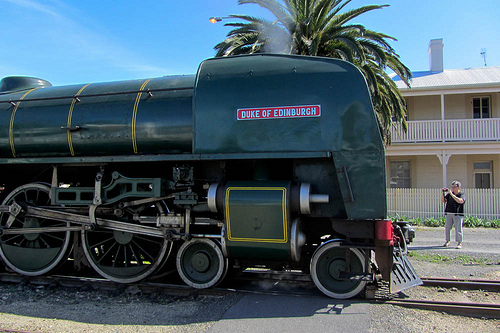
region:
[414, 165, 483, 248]
a man taking a picture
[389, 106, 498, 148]
the railings are white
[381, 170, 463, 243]
the railings are white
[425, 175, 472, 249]
Woman taking a picture.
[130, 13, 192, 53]
Bright blue sky above.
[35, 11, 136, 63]
Some light clouds in the sky.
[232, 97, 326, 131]
The name of the train.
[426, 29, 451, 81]
Chimney on the roof.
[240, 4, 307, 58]
Steam coming from the train.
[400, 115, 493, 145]
White balcony railing on the second floor.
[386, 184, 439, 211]
White fence in the yard.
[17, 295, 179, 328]
Gravel beside the train.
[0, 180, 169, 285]
Giant wheels on the train.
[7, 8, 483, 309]
A large rail train.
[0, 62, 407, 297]
A dark green locomotive train.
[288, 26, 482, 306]
Man taking picture of a locomotive train.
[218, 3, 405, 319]
Train riding pass a palm tree.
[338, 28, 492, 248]
Two-story beige house.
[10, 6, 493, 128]
Clear sky during the midday.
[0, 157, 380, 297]
Wheels of a train.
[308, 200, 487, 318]
Iron steel tracks.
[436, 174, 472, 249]
Man wearing a black shirt and holding a camera.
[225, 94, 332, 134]
Train with Duke of Edinburgh written on the side of it.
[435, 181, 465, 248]
A person standing and taking a picture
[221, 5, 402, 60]
The top of the palm tree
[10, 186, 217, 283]
The wheels to the bus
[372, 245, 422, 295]
The steam shovel on the train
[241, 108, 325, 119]
The red sign on the train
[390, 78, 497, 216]
The house behind the train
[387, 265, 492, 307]
The train tracks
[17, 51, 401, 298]
The large green train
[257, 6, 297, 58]
The steam coming fron the train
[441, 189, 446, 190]
The person standing behind the train's phone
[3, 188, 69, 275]
a clear plastic container filled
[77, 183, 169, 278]
the silver and black metal train wheel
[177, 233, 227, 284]
the silver and black metal train wheel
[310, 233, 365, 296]
the silver and black metal train wheel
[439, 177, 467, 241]
a person taking a picture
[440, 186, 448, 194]
the black camera of a person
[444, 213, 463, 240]
the khaki pants of a person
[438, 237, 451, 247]
the white shoe of a person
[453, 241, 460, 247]
the white shoe of a person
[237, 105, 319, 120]
the red and white sign of a train